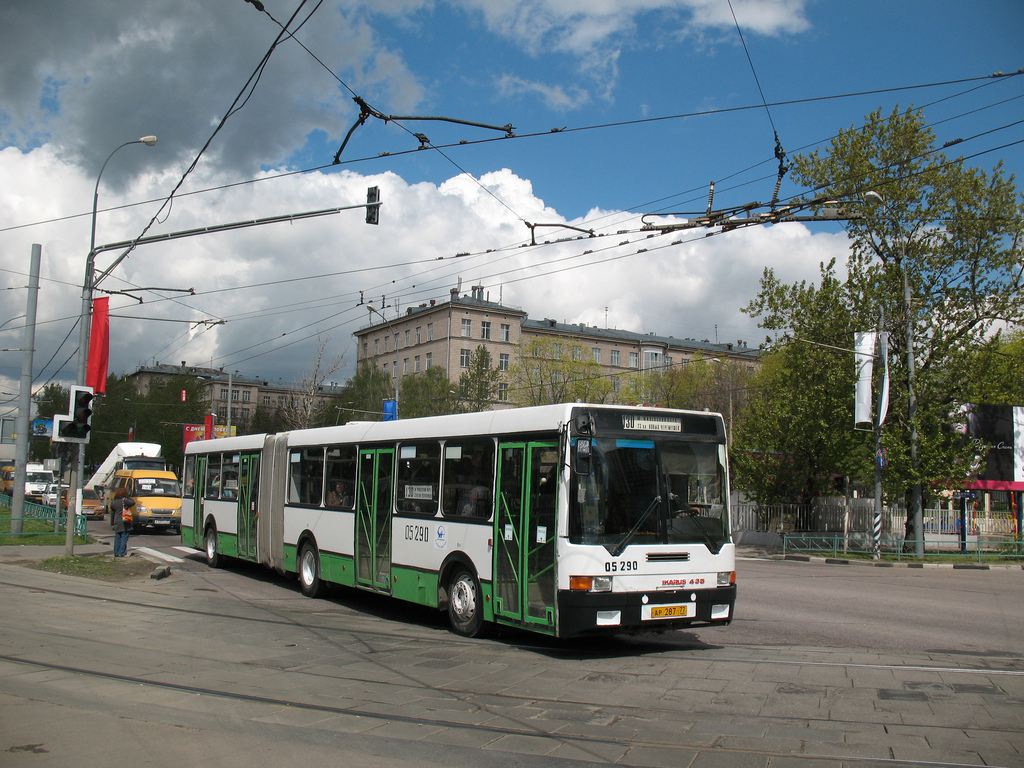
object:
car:
[0, 442, 184, 529]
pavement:
[0, 528, 1024, 768]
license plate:
[651, 605, 689, 618]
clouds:
[0, 0, 1022, 414]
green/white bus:
[181, 402, 748, 639]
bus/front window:
[570, 441, 731, 554]